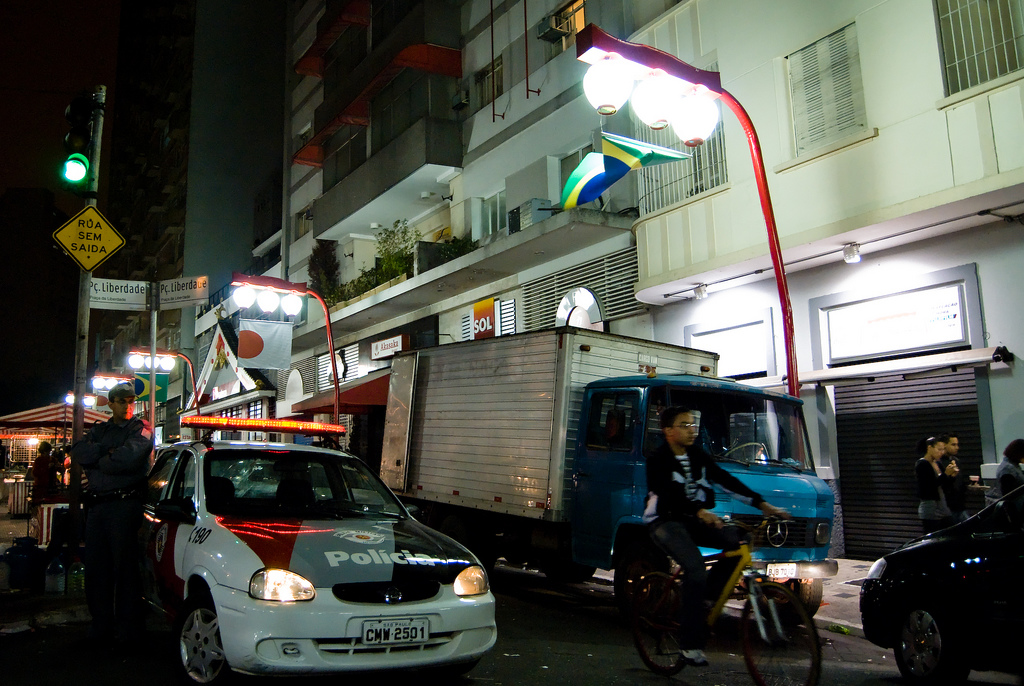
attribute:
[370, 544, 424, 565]
scene — outdoors 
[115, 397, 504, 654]
car — white , police 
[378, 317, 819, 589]
van — is blue, is white, is colored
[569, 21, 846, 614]
streetlight — is red, is colored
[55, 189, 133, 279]
streetsign — is colored, is yellow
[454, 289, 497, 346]
sign — is yellow, is colored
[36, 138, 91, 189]
stoplight — is green, is colored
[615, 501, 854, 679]
bike — is yellow, is colored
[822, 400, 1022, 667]
sedan — is black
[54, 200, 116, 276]
streetsign — is black, is yellow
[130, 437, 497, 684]
policecar — black, red, white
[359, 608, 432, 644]
licenseplate — white, black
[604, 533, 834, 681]
bike — yellow 